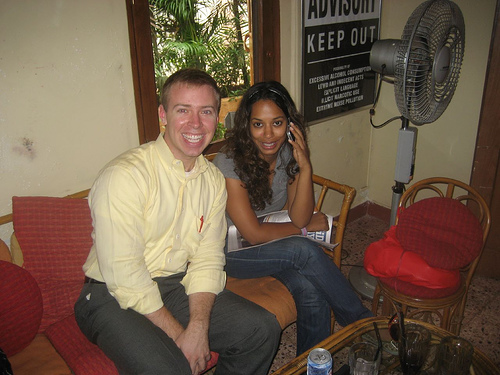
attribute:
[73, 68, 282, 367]
man — sitting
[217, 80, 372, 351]
woman — smiling, cell phone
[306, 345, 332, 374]
can — aluminum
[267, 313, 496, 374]
table — top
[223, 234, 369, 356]
pants — blue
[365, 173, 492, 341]
chair — brown, wicker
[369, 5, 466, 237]
fan — grey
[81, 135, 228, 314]
shirt — yellow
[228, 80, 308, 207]
hair — curly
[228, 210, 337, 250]
newspaper — held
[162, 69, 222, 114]
hair — blonde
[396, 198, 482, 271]
pillow — plaid